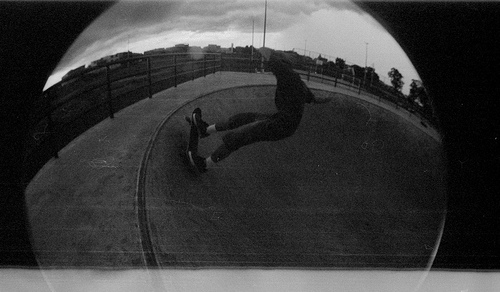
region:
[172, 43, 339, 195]
person on a skate board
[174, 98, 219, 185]
black skate board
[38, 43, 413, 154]
rounded black metal fencing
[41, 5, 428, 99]
cloudy grey over cast sky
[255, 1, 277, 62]
tall lamp pole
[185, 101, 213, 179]
black skate boarding shoes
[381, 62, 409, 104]
tall bushy tree in the distance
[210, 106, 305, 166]
tight black capri pants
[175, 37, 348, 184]
person skateboarding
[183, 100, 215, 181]
black skateboard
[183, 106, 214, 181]
black and white sneakers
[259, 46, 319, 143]
dark t-shirt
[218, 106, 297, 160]
pair of capri pants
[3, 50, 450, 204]
fence bordering skate park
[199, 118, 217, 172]
pair of white socks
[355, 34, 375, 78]
tall street lamp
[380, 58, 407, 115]
tall tree bordering skate park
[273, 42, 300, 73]
head of a person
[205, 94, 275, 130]
leg of a person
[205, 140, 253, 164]
leg of a person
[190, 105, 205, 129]
feet of a person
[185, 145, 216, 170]
feet of a person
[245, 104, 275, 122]
thigh of a person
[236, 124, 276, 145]
thigh of a person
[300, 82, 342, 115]
arm of a person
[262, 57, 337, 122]
body of a person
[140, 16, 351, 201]
person on a skateboard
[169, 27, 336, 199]
a skateboarder going up a ramp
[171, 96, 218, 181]
a skateboard going up a ramp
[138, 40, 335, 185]
a boy going up a ramp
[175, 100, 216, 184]
the feet of a skateboarder on a board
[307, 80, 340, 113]
the arm of a boy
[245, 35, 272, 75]
the arm of a boy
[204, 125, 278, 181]
the leg of a boy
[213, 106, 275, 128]
the leg of a boy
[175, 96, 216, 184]
the feet of a boy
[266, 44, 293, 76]
the head of a boy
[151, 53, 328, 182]
The person is riding a skateboard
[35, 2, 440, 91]
Dark clouds in the sky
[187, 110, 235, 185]
The socks are white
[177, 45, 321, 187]
The person is wearing socks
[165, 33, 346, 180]
man on a skateboard